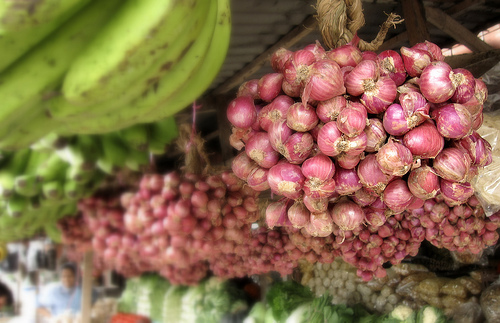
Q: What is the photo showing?
A: It is showing a market.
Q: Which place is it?
A: It is a market.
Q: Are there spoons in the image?
A: No, there are no spoons.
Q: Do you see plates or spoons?
A: No, there are no spoons or plates.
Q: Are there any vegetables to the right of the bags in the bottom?
A: Yes, there is a vegetable to the right of the bags.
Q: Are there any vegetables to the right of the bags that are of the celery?
A: Yes, there is a vegetable to the right of the bags.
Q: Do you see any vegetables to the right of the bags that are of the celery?
A: Yes, there is a vegetable to the right of the bags.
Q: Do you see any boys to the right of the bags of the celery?
A: No, there is a vegetable to the right of the bags.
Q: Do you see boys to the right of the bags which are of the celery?
A: No, there is a vegetable to the right of the bags.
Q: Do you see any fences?
A: No, there are no fences.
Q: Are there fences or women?
A: No, there are no fences or women.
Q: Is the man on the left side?
A: Yes, the man is on the left of the image.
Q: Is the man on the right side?
A: No, the man is on the left of the image.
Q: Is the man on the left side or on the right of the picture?
A: The man is on the left of the image.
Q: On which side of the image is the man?
A: The man is on the left of the image.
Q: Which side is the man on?
A: The man is on the left of the image.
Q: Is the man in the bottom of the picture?
A: Yes, the man is in the bottom of the image.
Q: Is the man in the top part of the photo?
A: No, the man is in the bottom of the image.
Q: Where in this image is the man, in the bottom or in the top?
A: The man is in the bottom of the image.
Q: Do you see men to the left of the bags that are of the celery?
A: Yes, there is a man to the left of the bags.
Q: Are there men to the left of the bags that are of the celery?
A: Yes, there is a man to the left of the bags.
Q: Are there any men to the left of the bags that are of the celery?
A: Yes, there is a man to the left of the bags.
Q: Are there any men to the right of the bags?
A: No, the man is to the left of the bags.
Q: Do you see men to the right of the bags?
A: No, the man is to the left of the bags.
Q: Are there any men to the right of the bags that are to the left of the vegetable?
A: No, the man is to the left of the bags.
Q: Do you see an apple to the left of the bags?
A: No, there is a man to the left of the bags.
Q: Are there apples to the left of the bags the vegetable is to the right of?
A: No, there is a man to the left of the bags.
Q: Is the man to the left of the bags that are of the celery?
A: Yes, the man is to the left of the bags.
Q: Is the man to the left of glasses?
A: No, the man is to the left of the bags.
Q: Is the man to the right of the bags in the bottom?
A: No, the man is to the left of the bags.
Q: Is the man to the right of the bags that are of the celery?
A: No, the man is to the left of the bags.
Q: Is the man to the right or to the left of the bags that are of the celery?
A: The man is to the left of the bags.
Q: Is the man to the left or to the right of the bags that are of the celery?
A: The man is to the left of the bags.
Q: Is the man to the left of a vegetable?
A: Yes, the man is to the left of a vegetable.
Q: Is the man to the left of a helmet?
A: No, the man is to the left of a vegetable.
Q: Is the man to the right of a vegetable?
A: No, the man is to the left of a vegetable.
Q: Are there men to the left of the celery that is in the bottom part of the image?
A: Yes, there is a man to the left of the celery.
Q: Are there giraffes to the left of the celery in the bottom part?
A: No, there is a man to the left of the celery.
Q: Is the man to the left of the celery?
A: Yes, the man is to the left of the celery.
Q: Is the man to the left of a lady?
A: No, the man is to the left of the celery.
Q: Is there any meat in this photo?
A: No, there is no meat.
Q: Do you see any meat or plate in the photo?
A: No, there are no meat or plates.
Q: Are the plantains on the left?
A: Yes, the plantains are on the left of the image.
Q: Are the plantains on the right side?
A: No, the plantains are on the left of the image.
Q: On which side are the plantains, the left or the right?
A: The plantains are on the left of the image.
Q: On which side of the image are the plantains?
A: The plantains are on the left of the image.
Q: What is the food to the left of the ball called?
A: The food is plantains.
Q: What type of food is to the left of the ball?
A: The food is plantains.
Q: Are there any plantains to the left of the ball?
A: Yes, there are plantains to the left of the ball.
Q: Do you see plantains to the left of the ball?
A: Yes, there are plantains to the left of the ball.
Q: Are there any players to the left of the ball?
A: No, there are plantains to the left of the ball.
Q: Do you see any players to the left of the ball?
A: No, there are plantains to the left of the ball.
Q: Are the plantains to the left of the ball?
A: Yes, the plantains are to the left of the ball.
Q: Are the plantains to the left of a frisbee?
A: No, the plantains are to the left of the ball.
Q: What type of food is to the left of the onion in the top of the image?
A: The food is plantains.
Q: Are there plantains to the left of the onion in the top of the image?
A: Yes, there are plantains to the left of the onion.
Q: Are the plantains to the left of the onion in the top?
A: Yes, the plantains are to the left of the onion.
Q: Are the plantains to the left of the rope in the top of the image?
A: Yes, the plantains are to the left of the rope.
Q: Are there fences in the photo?
A: No, there are no fences.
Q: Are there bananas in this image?
A: Yes, there are bananas.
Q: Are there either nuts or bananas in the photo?
A: Yes, there are bananas.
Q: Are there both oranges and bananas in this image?
A: No, there are bananas but no oranges.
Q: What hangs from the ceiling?
A: The bananas hang from the ceiling.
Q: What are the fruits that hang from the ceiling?
A: The fruits are bananas.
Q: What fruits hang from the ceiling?
A: The fruits are bananas.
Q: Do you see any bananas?
A: Yes, there are bananas.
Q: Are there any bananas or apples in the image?
A: Yes, there are bananas.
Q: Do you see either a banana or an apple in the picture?
A: Yes, there are bananas.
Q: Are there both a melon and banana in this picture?
A: No, there are bananas but no melons.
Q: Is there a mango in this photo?
A: No, there are no mangoes.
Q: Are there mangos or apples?
A: No, there are no mangos or apples.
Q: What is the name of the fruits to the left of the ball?
A: The fruits are bananas.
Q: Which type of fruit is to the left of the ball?
A: The fruits are bananas.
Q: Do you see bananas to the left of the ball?
A: Yes, there are bananas to the left of the ball.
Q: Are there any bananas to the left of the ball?
A: Yes, there are bananas to the left of the ball.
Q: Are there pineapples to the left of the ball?
A: No, there are bananas to the left of the ball.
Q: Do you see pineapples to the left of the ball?
A: No, there are bananas to the left of the ball.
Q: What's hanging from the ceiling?
A: The bananas are hanging from the ceiling.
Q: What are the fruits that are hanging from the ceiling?
A: The fruits are bananas.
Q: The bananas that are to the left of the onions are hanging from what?
A: The bananas are hanging from the ceiling.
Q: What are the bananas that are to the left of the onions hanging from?
A: The bananas are hanging from the ceiling.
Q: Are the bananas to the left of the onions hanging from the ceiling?
A: Yes, the bananas are hanging from the ceiling.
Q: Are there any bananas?
A: Yes, there are bananas.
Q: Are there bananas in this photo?
A: Yes, there are bananas.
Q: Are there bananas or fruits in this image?
A: Yes, there are bananas.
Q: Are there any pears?
A: No, there are no pears.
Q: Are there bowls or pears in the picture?
A: No, there are no pears or bowls.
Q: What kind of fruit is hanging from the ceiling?
A: The fruits are bananas.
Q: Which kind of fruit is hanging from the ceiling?
A: The fruits are bananas.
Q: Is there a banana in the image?
A: Yes, there are bananas.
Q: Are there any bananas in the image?
A: Yes, there are bananas.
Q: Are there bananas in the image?
A: Yes, there are bananas.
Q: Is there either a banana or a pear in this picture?
A: Yes, there are bananas.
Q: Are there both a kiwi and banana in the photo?
A: No, there are bananas but no kiwis.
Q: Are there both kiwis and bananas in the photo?
A: No, there are bananas but no kiwis.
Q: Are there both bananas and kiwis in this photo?
A: No, there are bananas but no kiwis.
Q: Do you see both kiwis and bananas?
A: No, there are bananas but no kiwis.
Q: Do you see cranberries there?
A: No, there are no cranberries.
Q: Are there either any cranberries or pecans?
A: No, there are no cranberries or pecans.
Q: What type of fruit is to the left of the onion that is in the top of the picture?
A: The fruits are bananas.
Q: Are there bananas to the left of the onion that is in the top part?
A: Yes, there are bananas to the left of the onion.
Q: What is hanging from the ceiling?
A: The bananas are hanging from the ceiling.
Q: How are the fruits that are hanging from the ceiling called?
A: The fruits are bananas.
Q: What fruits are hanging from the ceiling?
A: The fruits are bananas.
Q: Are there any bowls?
A: No, there are no bowls.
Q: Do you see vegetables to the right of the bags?
A: Yes, there is a vegetable to the right of the bags.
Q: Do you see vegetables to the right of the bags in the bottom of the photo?
A: Yes, there is a vegetable to the right of the bags.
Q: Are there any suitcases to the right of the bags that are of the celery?
A: No, there is a vegetable to the right of the bags.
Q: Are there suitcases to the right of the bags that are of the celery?
A: No, there is a vegetable to the right of the bags.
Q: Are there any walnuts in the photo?
A: No, there are no walnuts.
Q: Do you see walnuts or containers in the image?
A: No, there are no walnuts or containers.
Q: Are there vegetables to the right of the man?
A: Yes, there is a vegetable to the right of the man.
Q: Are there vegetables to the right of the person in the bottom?
A: Yes, there is a vegetable to the right of the man.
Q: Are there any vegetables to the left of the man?
A: No, the vegetable is to the right of the man.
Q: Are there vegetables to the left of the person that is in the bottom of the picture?
A: No, the vegetable is to the right of the man.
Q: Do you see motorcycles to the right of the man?
A: No, there is a vegetable to the right of the man.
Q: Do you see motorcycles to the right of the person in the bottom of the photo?
A: No, there is a vegetable to the right of the man.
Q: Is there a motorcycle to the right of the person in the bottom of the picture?
A: No, there is a vegetable to the right of the man.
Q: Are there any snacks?
A: No, there are no snacks.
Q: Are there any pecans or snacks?
A: No, there are no snacks or pecans.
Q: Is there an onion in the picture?
A: Yes, there is an onion.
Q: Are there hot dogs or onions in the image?
A: Yes, there is an onion.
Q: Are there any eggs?
A: No, there are no eggs.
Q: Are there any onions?
A: Yes, there is an onion.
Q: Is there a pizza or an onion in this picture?
A: Yes, there is an onion.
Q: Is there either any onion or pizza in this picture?
A: Yes, there is an onion.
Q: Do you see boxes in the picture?
A: No, there are no boxes.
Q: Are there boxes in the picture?
A: No, there are no boxes.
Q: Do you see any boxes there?
A: No, there are no boxes.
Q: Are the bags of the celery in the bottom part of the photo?
A: Yes, the bags are in the bottom of the image.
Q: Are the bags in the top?
A: No, the bags are in the bottom of the image.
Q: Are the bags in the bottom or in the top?
A: The bags are in the bottom of the image.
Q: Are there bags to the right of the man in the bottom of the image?
A: Yes, there are bags to the right of the man.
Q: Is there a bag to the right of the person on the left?
A: Yes, there are bags to the right of the man.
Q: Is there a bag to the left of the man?
A: No, the bags are to the right of the man.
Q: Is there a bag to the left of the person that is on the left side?
A: No, the bags are to the right of the man.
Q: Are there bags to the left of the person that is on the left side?
A: No, the bags are to the right of the man.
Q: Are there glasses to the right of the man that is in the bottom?
A: No, there are bags to the right of the man.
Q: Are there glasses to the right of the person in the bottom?
A: No, there are bags to the right of the man.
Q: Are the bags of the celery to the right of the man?
A: Yes, the bags are to the right of the man.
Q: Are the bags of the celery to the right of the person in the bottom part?
A: Yes, the bags are to the right of the man.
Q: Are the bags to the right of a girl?
A: No, the bags are to the right of the man.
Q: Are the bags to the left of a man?
A: No, the bags are to the right of a man.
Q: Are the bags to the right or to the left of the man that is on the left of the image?
A: The bags are to the right of the man.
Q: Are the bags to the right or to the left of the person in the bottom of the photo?
A: The bags are to the right of the man.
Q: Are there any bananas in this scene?
A: Yes, there are bananas.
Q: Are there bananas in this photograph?
A: Yes, there are bananas.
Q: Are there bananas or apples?
A: Yes, there are bananas.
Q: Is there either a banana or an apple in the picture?
A: Yes, there are bananas.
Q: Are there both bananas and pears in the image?
A: No, there are bananas but no pears.